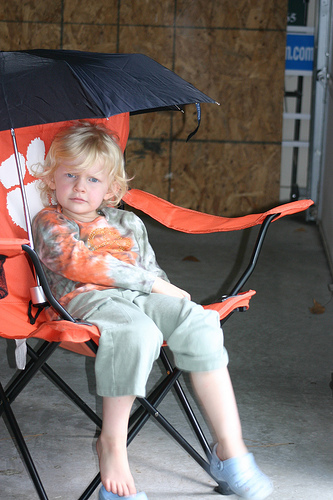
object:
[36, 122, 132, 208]
blonde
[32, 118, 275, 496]
child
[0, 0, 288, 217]
wall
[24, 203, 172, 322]
shirt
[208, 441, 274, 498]
croc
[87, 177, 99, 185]
eye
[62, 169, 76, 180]
eye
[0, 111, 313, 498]
chair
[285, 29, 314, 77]
sign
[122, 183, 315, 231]
restarm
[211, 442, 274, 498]
shoe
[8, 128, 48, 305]
shaft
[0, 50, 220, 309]
umbrella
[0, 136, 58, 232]
paw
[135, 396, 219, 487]
leg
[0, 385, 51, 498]
leg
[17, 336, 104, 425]
leg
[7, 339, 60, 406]
leg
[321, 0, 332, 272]
door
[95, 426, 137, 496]
foot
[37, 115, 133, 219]
hair